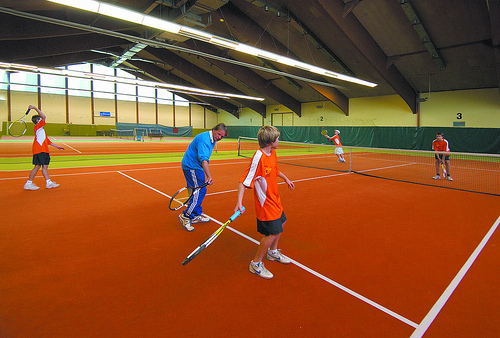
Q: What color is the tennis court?
A: Orange.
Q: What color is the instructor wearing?
A: Blue.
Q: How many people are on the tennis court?
A: 5.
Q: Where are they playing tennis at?
A: Gym.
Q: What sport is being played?
A: Tennis.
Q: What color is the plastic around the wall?
A: Green.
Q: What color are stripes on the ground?
A: White.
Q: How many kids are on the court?
A: 4.